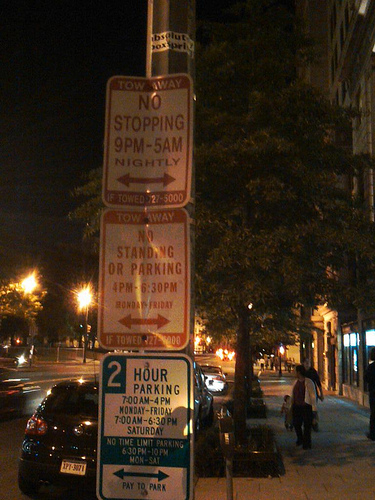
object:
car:
[183, 355, 244, 405]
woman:
[283, 364, 324, 463]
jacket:
[287, 373, 330, 414]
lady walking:
[290, 367, 322, 430]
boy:
[279, 393, 295, 432]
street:
[1, 421, 21, 499]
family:
[276, 353, 327, 451]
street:
[198, 361, 371, 494]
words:
[105, 357, 185, 493]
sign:
[103, 73, 191, 211]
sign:
[98, 213, 190, 349]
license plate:
[56, 457, 89, 477]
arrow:
[111, 465, 168, 489]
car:
[16, 377, 98, 496]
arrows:
[116, 311, 172, 330]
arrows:
[115, 167, 176, 188]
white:
[128, 358, 180, 390]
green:
[100, 429, 183, 476]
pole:
[141, 2, 198, 77]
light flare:
[77, 286, 97, 310]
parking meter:
[215, 403, 235, 497]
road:
[0, 353, 234, 497]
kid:
[276, 391, 293, 431]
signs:
[100, 349, 191, 497]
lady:
[283, 362, 323, 448]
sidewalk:
[252, 355, 373, 496]